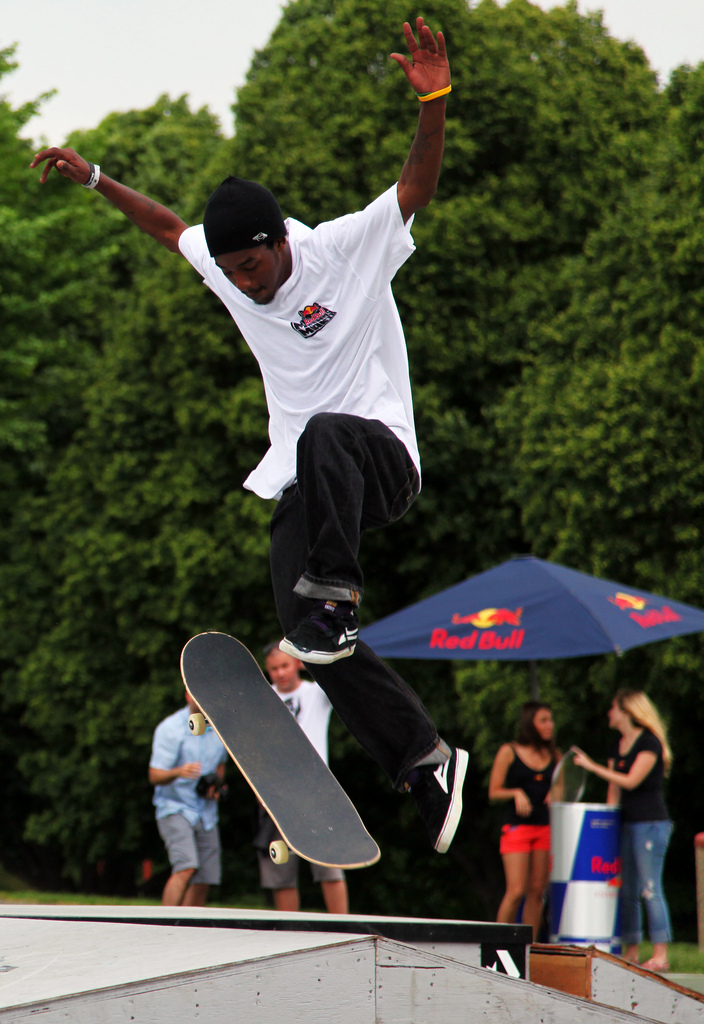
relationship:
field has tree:
[0, 867, 703, 971] [473, 2, 702, 933]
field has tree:
[0, 867, 703, 971] [6, 0, 702, 923]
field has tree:
[0, 867, 703, 971] [149, 0, 524, 920]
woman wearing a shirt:
[575, 687, 673, 973] [608, 730, 673, 825]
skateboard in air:
[173, 630, 381, 874] [89, 613, 532, 923]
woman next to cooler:
[575, 687, 673, 973] [542, 741, 619, 961]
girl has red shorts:
[487, 694, 563, 942] [493, 819, 560, 853]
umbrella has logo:
[343, 553, 702, 669] [431, 619, 529, 658]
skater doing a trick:
[26, 14, 472, 851] [27, 14, 481, 874]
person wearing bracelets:
[26, 14, 472, 851] [410, 81, 462, 110]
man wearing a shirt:
[26, 14, 472, 851] [177, 177, 439, 498]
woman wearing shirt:
[575, 687, 673, 973] [608, 730, 673, 825]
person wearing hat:
[26, 14, 472, 851] [202, 170, 288, 261]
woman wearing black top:
[575, 687, 673, 973] [608, 730, 673, 825]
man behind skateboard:
[260, 634, 361, 922] [173, 630, 381, 874]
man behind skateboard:
[148, 680, 227, 909] [173, 630, 381, 874]